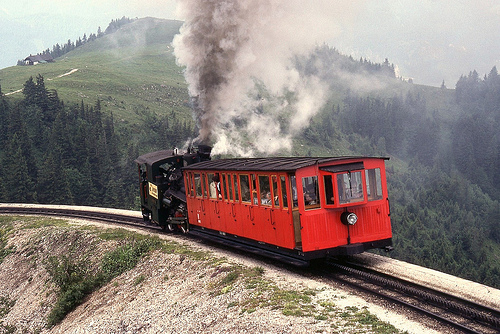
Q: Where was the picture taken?
A: It was taken at the railroad.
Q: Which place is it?
A: It is a railroad.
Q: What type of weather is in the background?
A: It is overcast.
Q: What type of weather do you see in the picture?
A: It is overcast.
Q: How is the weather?
A: It is overcast.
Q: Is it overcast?
A: Yes, it is overcast.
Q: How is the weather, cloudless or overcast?
A: It is overcast.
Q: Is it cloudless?
A: No, it is overcast.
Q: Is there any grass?
A: Yes, there is grass.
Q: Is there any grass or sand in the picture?
A: Yes, there is grass.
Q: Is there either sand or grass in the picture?
A: Yes, there is grass.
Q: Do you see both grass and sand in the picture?
A: No, there is grass but no sand.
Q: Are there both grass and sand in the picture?
A: No, there is grass but no sand.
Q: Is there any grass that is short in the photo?
A: Yes, there is short grass.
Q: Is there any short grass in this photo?
A: Yes, there is short grass.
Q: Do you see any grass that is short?
A: Yes, there is short grass.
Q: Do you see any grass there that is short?
A: Yes, there is grass that is short.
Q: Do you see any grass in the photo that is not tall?
A: Yes, there is short grass.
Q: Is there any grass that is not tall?
A: Yes, there is short grass.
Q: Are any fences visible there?
A: No, there are no fences.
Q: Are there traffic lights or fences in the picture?
A: No, there are no fences or traffic lights.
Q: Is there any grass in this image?
A: Yes, there is grass.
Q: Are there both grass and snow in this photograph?
A: No, there is grass but no snow.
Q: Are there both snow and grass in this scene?
A: No, there is grass but no snow.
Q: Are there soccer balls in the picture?
A: No, there are no soccer balls.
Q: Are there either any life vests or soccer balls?
A: No, there are no soccer balls or life vests.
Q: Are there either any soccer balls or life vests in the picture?
A: No, there are no soccer balls or life vests.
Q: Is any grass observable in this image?
A: Yes, there is grass.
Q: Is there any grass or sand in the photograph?
A: Yes, there is grass.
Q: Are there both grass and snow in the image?
A: No, there is grass but no snow.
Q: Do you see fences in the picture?
A: No, there are no fences.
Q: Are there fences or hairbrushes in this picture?
A: No, there are no fences or hairbrushes.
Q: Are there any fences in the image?
A: No, there are no fences.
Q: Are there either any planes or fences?
A: No, there are no fences or planes.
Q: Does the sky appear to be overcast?
A: Yes, the sky is overcast.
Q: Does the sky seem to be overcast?
A: Yes, the sky is overcast.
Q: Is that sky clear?
A: No, the sky is overcast.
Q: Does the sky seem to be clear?
A: No, the sky is overcast.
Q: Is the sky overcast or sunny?
A: The sky is overcast.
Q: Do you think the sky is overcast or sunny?
A: The sky is overcast.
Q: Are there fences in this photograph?
A: No, there are no fences.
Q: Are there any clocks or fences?
A: No, there are no fences or clocks.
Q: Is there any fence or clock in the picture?
A: No, there are no fences or clocks.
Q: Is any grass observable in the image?
A: Yes, there is grass.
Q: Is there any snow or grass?
A: Yes, there is grass.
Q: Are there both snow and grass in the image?
A: No, there is grass but no snow.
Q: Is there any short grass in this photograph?
A: Yes, there is short grass.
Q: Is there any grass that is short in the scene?
A: Yes, there is short grass.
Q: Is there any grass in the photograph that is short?
A: Yes, there is grass that is short.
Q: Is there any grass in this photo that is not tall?
A: Yes, there is short grass.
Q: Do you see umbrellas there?
A: No, there are no umbrellas.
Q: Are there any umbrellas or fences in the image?
A: No, there are no umbrellas or fences.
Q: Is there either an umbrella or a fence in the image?
A: No, there are no umbrellas or fences.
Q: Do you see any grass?
A: Yes, there is grass.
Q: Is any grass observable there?
A: Yes, there is grass.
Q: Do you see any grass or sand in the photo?
A: Yes, there is grass.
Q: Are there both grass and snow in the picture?
A: No, there is grass but no snow.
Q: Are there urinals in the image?
A: No, there are no urinals.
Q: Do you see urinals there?
A: No, there are no urinals.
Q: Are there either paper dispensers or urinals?
A: No, there are no urinals or paper dispensers.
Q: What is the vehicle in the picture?
A: The vehicle is a car.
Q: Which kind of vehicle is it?
A: The vehicle is a car.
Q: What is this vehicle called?
A: This is a car.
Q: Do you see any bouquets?
A: No, there are no bouquets.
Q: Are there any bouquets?
A: No, there are no bouquets.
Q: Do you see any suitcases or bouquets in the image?
A: No, there are no bouquets or suitcases.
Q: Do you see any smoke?
A: Yes, there is smoke.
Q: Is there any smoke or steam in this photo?
A: Yes, there is smoke.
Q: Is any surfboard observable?
A: No, there are no surfboards.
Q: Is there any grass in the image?
A: Yes, there is grass.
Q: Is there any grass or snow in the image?
A: Yes, there is grass.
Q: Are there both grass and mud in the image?
A: No, there is grass but no mud.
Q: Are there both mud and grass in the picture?
A: No, there is grass but no mud.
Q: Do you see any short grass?
A: Yes, there is short grass.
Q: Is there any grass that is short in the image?
A: Yes, there is short grass.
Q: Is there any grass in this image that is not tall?
A: Yes, there is short grass.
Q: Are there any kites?
A: No, there are no kites.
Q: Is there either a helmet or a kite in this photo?
A: No, there are no kites or helmets.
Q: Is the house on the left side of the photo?
A: Yes, the house is on the left of the image.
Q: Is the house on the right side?
A: No, the house is on the left of the image.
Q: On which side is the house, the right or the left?
A: The house is on the left of the image.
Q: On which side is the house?
A: The house is on the left of the image.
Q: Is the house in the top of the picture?
A: Yes, the house is in the top of the image.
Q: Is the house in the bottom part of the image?
A: No, the house is in the top of the image.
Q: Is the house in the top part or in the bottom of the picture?
A: The house is in the top of the image.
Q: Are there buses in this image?
A: No, there are no buses.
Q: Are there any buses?
A: No, there are no buses.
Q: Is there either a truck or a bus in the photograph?
A: No, there are no buses or trucks.